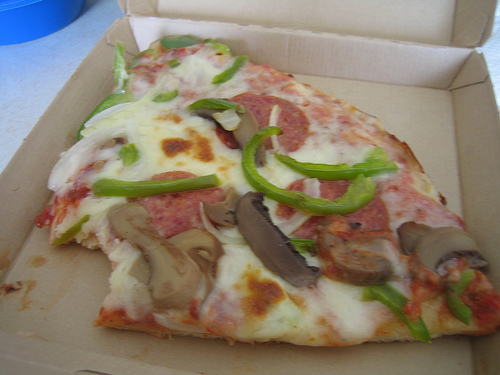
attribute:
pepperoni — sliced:
[273, 172, 393, 250]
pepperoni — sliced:
[213, 88, 314, 157]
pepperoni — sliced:
[124, 167, 228, 244]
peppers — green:
[356, 275, 438, 349]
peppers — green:
[88, 172, 223, 199]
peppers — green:
[238, 122, 380, 219]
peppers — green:
[270, 143, 403, 183]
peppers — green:
[210, 51, 252, 87]